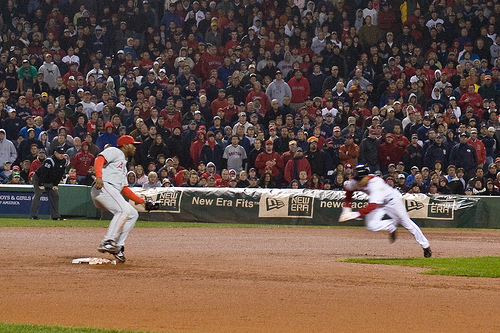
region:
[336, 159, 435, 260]
player running to the base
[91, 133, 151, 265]
fielder standing on the base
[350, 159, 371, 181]
helmet on a player's head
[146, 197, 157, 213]
black glove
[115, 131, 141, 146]
hat on a man's head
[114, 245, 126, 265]
fielder's foot near the base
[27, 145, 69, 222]
umpire wearing black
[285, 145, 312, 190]
Person in the stands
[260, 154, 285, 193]
Person in the stands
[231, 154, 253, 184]
Person in the stands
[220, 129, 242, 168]
Person in the stands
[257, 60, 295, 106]
Person in the stands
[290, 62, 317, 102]
Person in the stands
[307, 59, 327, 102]
Person in the stands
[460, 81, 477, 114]
Person in the stands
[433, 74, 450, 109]
Person in the stands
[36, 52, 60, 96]
Person in the stands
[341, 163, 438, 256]
baseball player running to the base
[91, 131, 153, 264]
baseball player trying to catch ball and tag the base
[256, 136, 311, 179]
spectators in red jackets and sweatshirts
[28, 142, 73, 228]
umpire watches the play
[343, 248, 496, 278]
green grass of the infield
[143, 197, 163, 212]
black leather glove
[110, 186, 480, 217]
advertising banner on the wall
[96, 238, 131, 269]
pair of black cleats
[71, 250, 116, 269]
white canvas base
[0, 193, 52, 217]
blue advertising banner on wall behind umpire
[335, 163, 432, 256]
Baseball player diving towards second base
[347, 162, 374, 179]
Black helmet on diving baseball player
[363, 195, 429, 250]
White pants on diving baseball player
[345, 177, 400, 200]
White jersey on diving baseball player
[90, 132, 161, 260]
Infielder preparing for catch in baseball game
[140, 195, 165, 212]
Dark colored glove on baseball infielder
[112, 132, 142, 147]
Red cap on baseball infielder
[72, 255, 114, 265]
White second base on a baseball field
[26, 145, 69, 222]
Umpire in dark clothing at baseball game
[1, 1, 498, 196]
Spectators of a baseball game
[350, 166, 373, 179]
The black helmet the player is wearing.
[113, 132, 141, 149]
The red hat the player is wearing.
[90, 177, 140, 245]
The pants the player in the red hat is wearing.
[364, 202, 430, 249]
The pants the player in the black helmet is wearing.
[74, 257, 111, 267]
The base behind the player.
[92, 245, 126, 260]
The sneakers of the player near the base.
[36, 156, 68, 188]
The black jacket the umpire is wearing.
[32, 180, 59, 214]
The gray pants the umpire is wearing.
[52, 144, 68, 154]
The black hat the umpire is wearing.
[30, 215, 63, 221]
The black shoes the umpire is wearing.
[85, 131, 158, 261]
a baseball player on base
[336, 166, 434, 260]
a baseball player running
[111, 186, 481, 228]
a stadium banner advertisement